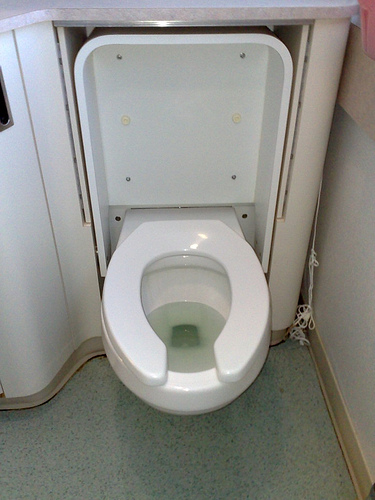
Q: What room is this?
A: Bathroom.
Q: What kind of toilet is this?
A: Fold up.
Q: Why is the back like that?
A: So the toilet and fold.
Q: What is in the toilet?
A: Water.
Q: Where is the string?
A: Between the wall.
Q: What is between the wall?
A: A string.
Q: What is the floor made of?
A: Linoleum.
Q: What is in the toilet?
A: Water.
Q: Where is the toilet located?
A: In the bathroom.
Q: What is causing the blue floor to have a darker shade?
A: A shadow.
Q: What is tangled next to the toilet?
A: The white string.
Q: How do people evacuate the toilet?
A: They flush it.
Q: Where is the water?
A: In the toilet bowl.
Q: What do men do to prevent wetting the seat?
A: Lift the seat.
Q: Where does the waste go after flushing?
A: Down the hole.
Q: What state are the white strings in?
A: Tangled.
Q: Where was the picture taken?
A: Inside of a portable restroom.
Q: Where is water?
A: Inside the toilet bowl.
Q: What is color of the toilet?
A: White.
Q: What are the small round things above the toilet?
A: Screws.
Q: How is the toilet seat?
A: Down.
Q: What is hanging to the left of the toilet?
A: Tangled string.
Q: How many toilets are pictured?
A: One.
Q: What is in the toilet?
A: Water.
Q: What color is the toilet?
A: White.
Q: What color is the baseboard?
A: Tan.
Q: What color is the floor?
A: Green.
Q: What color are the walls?
A: White.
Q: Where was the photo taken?
A: In a bathroom.